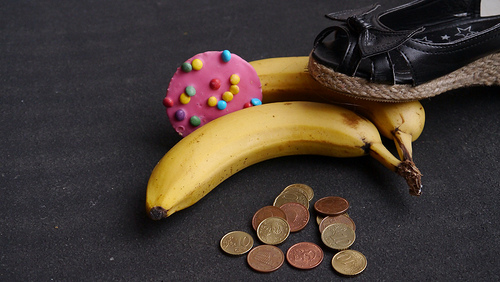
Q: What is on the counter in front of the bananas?
A: Coins.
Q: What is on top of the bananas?
A: Shoe.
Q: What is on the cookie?
A: Sprinkles.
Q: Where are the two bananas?
A: Counter.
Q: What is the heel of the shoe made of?
A: Straw.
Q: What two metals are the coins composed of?
A: Copper and Silver.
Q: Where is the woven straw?
A: Shoe.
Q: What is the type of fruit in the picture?
A: Bananas.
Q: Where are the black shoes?
A: On the banana.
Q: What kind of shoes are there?
A: Women's sandals.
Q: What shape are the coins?
A: Round.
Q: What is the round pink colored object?
A: A cookie.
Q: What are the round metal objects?
A: Coins.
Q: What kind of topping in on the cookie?
A: Candy.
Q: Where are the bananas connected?
A: At the stems.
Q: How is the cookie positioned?
A: Between the bananas.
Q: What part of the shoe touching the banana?
A: The sole.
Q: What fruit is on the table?
A: Bananas.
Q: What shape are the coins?
A: Round.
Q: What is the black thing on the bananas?
A: A shoe.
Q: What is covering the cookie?
A: Sprinkles.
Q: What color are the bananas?
A: Yellow.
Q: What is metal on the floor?
A: Coins.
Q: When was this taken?
A: Daytime.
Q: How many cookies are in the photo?
A: 1.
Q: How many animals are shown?
A: 0.